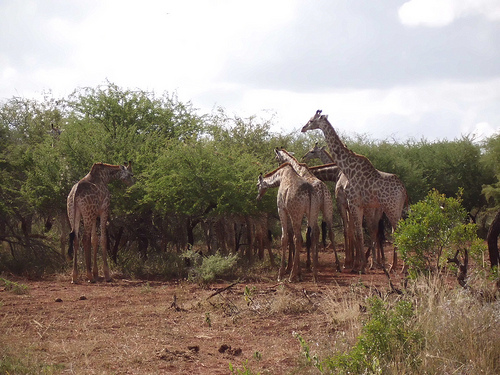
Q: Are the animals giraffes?
A: Yes, all the animals are giraffes.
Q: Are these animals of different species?
A: No, all the animals are giraffes.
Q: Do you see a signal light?
A: No, there are no traffic lights.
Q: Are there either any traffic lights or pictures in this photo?
A: No, there are no traffic lights or pictures.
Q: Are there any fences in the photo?
A: No, there are no fences.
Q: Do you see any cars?
A: No, there are no cars.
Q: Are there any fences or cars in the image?
A: No, there are no cars or fences.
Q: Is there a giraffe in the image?
A: Yes, there is a giraffe.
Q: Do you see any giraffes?
A: Yes, there is a giraffe.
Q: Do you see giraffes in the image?
A: Yes, there is a giraffe.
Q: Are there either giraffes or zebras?
A: Yes, there is a giraffe.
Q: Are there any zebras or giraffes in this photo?
A: Yes, there is a giraffe.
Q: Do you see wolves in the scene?
A: No, there are no wolves.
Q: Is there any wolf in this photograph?
A: No, there are no wolves.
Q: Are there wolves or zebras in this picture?
A: No, there are no wolves or zebras.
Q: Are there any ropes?
A: No, there are no ropes.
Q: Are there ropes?
A: No, there are no ropes.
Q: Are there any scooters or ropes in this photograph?
A: No, there are no ropes or scooters.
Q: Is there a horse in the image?
A: No, there are no horses.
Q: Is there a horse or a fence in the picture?
A: No, there are no horses or fences.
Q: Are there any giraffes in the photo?
A: Yes, there is a giraffe.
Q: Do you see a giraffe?
A: Yes, there is a giraffe.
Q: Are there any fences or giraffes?
A: Yes, there is a giraffe.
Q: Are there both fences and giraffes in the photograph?
A: No, there is a giraffe but no fences.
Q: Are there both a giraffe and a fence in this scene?
A: No, there is a giraffe but no fences.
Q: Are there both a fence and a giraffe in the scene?
A: No, there is a giraffe but no fences.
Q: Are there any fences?
A: No, there are no fences.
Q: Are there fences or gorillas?
A: No, there are no fences or gorillas.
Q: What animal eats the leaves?
A: The giraffe eats the leaves.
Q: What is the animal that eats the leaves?
A: The animal is a giraffe.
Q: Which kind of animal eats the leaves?
A: The animal is a giraffe.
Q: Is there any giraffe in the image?
A: Yes, there is a giraffe.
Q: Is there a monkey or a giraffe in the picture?
A: Yes, there is a giraffe.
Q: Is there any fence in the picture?
A: No, there are no fences.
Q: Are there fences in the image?
A: No, there are no fences.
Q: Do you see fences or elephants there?
A: No, there are no fences or elephants.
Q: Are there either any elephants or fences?
A: No, there are no fences or elephants.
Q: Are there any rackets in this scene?
A: No, there are no rackets.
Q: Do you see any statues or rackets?
A: No, there are no rackets or statues.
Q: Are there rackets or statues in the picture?
A: No, there are no rackets or statues.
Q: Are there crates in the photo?
A: No, there are no crates.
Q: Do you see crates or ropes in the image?
A: No, there are no crates or ropes.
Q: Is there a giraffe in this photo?
A: Yes, there is a giraffe.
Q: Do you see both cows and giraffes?
A: No, there is a giraffe but no cows.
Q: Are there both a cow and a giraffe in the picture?
A: No, there is a giraffe but no cows.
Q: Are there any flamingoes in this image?
A: No, there are no flamingoes.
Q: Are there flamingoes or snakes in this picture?
A: No, there are no flamingoes or snakes.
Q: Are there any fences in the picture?
A: No, there are no fences.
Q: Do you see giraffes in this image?
A: Yes, there are giraffes.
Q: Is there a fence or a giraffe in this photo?
A: Yes, there are giraffes.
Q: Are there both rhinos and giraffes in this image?
A: No, there are giraffes but no rhinos.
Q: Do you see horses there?
A: No, there are no horses.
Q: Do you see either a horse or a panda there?
A: No, there are no horses or pandas.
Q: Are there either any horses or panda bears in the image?
A: No, there are no horses or panda bears.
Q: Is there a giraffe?
A: Yes, there is a giraffe.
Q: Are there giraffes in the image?
A: Yes, there is a giraffe.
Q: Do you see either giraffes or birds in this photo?
A: Yes, there is a giraffe.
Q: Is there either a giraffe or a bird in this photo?
A: Yes, there is a giraffe.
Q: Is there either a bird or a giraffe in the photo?
A: Yes, there is a giraffe.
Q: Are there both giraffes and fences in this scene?
A: No, there is a giraffe but no fences.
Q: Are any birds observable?
A: No, there are no birds.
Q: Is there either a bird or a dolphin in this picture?
A: No, there are no birds or dolphins.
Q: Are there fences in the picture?
A: No, there are no fences.